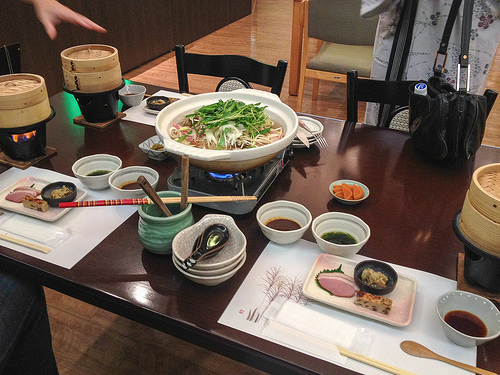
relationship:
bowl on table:
[434, 290, 497, 347] [6, 67, 498, 370]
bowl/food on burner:
[154, 88, 299, 174] [164, 146, 290, 217]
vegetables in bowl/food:
[180, 95, 266, 148] [154, 88, 299, 174]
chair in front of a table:
[170, 49, 291, 107] [6, 67, 498, 370]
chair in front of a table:
[337, 65, 493, 163] [6, 67, 498, 370]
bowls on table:
[172, 213, 244, 283] [6, 67, 498, 370]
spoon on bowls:
[173, 225, 227, 272] [172, 213, 247, 286]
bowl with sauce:
[261, 200, 313, 249] [270, 214, 299, 230]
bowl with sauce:
[315, 214, 365, 252] [324, 231, 356, 249]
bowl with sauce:
[255, 200, 313, 245] [266, 214, 300, 228]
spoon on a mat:
[399, 334, 480, 372] [217, 234, 493, 372]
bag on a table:
[410, 5, 486, 168] [6, 67, 498, 370]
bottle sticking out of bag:
[412, 78, 433, 98] [404, 5, 485, 163]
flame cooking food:
[202, 173, 240, 187] [164, 89, 287, 150]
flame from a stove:
[10, 127, 42, 143] [4, 125, 45, 161]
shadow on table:
[99, 242, 217, 325] [6, 67, 498, 370]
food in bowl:
[168, 102, 288, 152] [152, 85, 302, 183]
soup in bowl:
[446, 302, 487, 331] [437, 294, 493, 346]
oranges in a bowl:
[330, 178, 357, 205] [321, 171, 368, 207]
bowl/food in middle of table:
[154, 88, 299, 174] [6, 67, 498, 370]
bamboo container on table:
[60, 44, 123, 93] [6, 67, 498, 370]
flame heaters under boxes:
[10, 87, 126, 165] [2, 47, 118, 137]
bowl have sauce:
[312, 211, 371, 258] [266, 219, 299, 232]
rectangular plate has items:
[0, 172, 88, 223] [6, 180, 84, 215]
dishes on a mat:
[296, 249, 453, 338] [217, 241, 477, 375]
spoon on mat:
[399, 339, 500, 375] [211, 228, 482, 373]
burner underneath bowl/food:
[166, 141, 293, 215] [150, 86, 300, 161]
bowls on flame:
[172, 213, 247, 286] [208, 172, 240, 180]